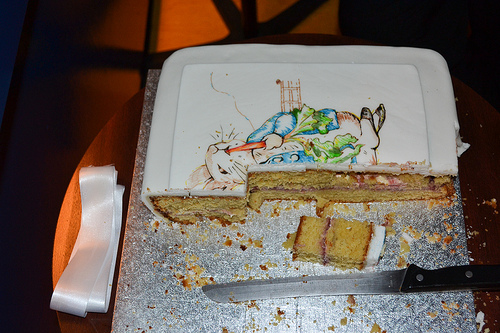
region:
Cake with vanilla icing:
[140, 60, 497, 195]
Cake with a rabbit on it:
[140, 33, 462, 258]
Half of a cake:
[160, 60, 445, 280]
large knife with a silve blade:
[201, 270, 492, 312]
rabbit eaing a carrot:
[190, 137, 310, 175]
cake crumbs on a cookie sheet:
[137, 213, 497, 301]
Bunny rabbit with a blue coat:
[200, 95, 396, 186]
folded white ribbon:
[50, 162, 135, 317]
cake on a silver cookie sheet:
[140, 72, 425, 327]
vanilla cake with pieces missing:
[147, 96, 462, 304]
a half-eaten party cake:
[52, 15, 485, 330]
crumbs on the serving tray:
[170, 256, 210, 282]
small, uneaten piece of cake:
[290, 205, 385, 265]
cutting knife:
[202, 262, 494, 292]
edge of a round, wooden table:
[46, 190, 71, 235]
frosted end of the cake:
[166, 37, 438, 62]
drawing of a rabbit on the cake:
[195, 105, 390, 187]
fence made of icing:
[275, 71, 305, 106]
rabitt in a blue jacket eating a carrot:
[198, 105, 388, 163]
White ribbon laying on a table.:
[50, 128, 137, 320]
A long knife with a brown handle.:
[193, 255, 498, 310]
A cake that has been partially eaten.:
[121, 38, 476, 331]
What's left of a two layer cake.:
[141, 38, 460, 266]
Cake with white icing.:
[148, 33, 461, 211]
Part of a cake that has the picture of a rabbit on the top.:
[155, 56, 453, 203]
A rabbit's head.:
[182, 120, 262, 195]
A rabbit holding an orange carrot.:
[190, 96, 380, 181]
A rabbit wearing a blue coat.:
[190, 93, 371, 188]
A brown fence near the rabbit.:
[271, 73, 308, 115]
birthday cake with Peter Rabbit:
[127, 28, 467, 230]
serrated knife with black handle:
[200, 262, 492, 315]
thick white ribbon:
[51, 162, 124, 327]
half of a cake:
[141, 50, 473, 327]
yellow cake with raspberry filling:
[289, 210, 394, 271]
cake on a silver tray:
[115, 35, 459, 332]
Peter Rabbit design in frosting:
[185, 73, 401, 191]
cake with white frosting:
[137, 37, 467, 229]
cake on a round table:
[49, 6, 496, 330]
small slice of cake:
[288, 200, 402, 268]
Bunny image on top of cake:
[188, 67, 380, 190]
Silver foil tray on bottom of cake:
[110, 195, 475, 331]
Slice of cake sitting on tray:
[294, 211, 385, 266]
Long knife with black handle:
[198, 262, 498, 303]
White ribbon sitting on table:
[48, 158, 125, 319]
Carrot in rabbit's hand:
[221, 132, 283, 153]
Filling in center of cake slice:
[317, 218, 333, 262]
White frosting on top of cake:
[379, 44, 456, 172]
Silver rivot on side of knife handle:
[415, 271, 424, 281]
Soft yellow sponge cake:
[327, 218, 370, 265]